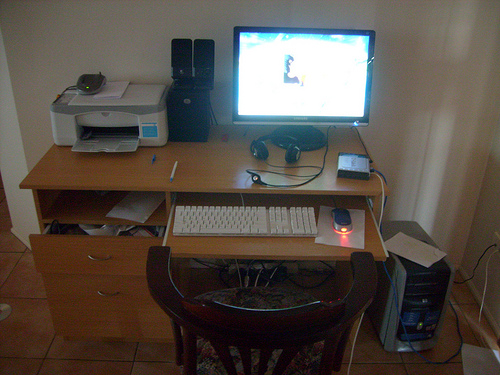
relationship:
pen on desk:
[144, 153, 202, 195] [4, 94, 405, 249]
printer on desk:
[12, 44, 190, 166] [4, 94, 405, 249]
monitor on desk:
[207, 18, 393, 147] [4, 94, 405, 249]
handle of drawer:
[87, 246, 121, 265] [11, 205, 162, 284]